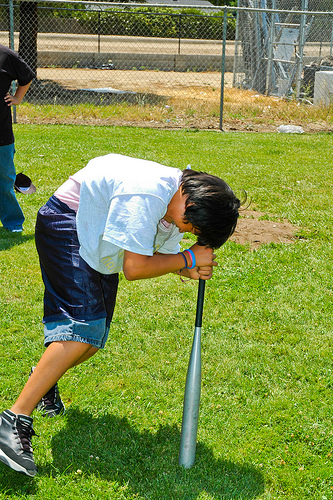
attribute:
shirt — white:
[96, 185, 140, 207]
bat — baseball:
[168, 277, 216, 462]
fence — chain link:
[0, 0, 332, 132]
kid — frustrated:
[7, 153, 237, 456]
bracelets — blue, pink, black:
[176, 245, 197, 275]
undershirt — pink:
[52, 164, 85, 212]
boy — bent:
[8, 128, 242, 469]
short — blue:
[33, 217, 108, 346]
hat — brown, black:
[13, 165, 41, 203]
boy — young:
[1, 149, 246, 475]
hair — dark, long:
[167, 153, 254, 253]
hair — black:
[163, 167, 253, 261]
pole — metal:
[94, 9, 103, 51]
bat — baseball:
[172, 267, 239, 482]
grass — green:
[1, 121, 332, 498]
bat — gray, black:
[177, 238, 211, 469]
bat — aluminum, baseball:
[177, 237, 208, 472]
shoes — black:
[4, 363, 72, 483]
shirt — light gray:
[52, 153, 198, 289]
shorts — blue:
[34, 191, 123, 345]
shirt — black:
[2, 37, 29, 150]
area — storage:
[253, 6, 319, 118]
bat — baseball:
[180, 297, 212, 480]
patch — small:
[284, 121, 298, 134]